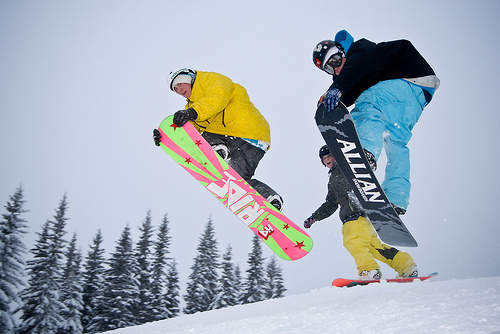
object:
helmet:
[167, 67, 196, 92]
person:
[167, 65, 283, 211]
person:
[301, 143, 422, 278]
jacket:
[186, 71, 273, 148]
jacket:
[337, 37, 442, 107]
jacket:
[310, 166, 372, 222]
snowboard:
[331, 271, 443, 288]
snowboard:
[314, 95, 421, 249]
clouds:
[0, 0, 500, 229]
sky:
[1, 1, 500, 286]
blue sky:
[1, 0, 500, 280]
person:
[309, 20, 438, 220]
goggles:
[321, 48, 348, 75]